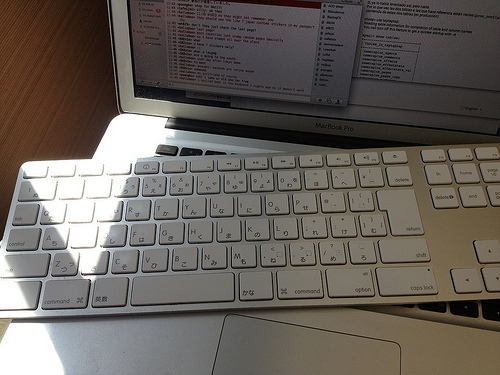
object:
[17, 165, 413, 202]
keys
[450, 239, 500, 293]
buttons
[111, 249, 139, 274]
letter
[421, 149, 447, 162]
keyboard button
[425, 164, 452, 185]
keyboard button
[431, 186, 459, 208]
keyboard button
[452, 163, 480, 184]
keyboard button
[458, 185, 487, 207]
keyboard button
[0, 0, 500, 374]
shadow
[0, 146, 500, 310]
buttons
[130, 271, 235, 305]
spacebar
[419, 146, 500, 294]
keypad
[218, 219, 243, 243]
letter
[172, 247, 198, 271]
letter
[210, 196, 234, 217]
letter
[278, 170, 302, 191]
letter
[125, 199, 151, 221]
letter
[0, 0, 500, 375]
computer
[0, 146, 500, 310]
letters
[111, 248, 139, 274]
key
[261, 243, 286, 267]
key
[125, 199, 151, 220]
key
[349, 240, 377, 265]
key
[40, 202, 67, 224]
white key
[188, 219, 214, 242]
white letter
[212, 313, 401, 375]
mousepad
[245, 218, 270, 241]
key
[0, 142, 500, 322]
white keyboard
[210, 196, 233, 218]
key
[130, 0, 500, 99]
words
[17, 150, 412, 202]
buttons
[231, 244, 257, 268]
letter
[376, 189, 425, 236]
button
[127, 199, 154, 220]
white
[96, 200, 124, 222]
key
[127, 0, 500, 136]
monitor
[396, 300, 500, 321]
buttons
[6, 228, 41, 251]
key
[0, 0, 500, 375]
table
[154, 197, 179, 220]
key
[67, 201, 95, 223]
key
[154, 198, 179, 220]
letter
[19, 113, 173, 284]
light reflection